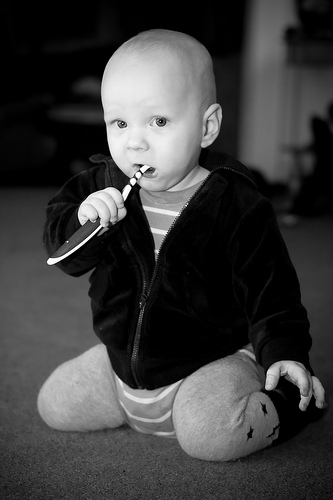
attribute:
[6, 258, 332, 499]
floor — clean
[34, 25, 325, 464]
baby — bald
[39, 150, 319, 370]
jacket — black